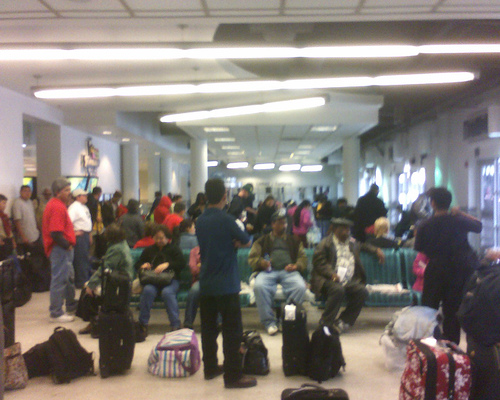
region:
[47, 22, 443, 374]
this is a transit area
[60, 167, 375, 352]
these people are waiting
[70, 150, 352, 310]
this is a group of people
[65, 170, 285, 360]
the people are traveling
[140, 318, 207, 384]
these are traveling bags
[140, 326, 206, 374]
the bag is striped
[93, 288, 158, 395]
this luggage is black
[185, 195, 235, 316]
this is a man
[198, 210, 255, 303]
the man has a blue shirt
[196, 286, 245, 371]
the man has black pants on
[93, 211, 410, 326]
people sitting on a bench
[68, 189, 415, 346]
people sitting on a bench at a airport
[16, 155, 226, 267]
people standing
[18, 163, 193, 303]
people standing at a airport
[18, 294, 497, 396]
bags and suitcases on the floor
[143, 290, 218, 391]
a striped duffle bag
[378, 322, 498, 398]
a red and black suitcase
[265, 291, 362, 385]
two black suitcases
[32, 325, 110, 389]
a black backpack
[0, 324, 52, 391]
a cheetah print bag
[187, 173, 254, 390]
man standing in middle of airport with arms crossed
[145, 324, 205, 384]
purple and blue striped dufle bag on ground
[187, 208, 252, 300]
blue shirt on man standing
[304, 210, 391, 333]
man sitting on green bench in brown hat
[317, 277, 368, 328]
brown trousers on black man sitting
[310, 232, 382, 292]
brown jacket on black man with white shirt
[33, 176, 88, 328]
man standing with red shirt and blue jeans with hand in pocket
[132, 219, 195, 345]
woman sitting with blue jeans and black coat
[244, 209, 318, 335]
African American man sitting in blue jeans holding water bottle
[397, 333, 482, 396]
red floral luggage in foreground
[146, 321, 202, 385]
Rainbow bag on the ground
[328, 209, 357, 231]
man wearing a black hat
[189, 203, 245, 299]
man wearing a blue shirt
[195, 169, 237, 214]
man with black hair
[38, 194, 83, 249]
man wearing a red shirt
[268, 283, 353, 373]
luggage on the ground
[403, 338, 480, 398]
red luggage on the ground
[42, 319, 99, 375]
backpack on the ground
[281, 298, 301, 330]
tag on a suitcase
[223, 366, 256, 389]
man wearing brown shoes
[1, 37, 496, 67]
bright white fluorescent tube lighting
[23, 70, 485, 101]
bright white fluorescent tube lighting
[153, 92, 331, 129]
bright white fluorescent tube lighting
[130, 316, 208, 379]
purple, yellow, and blue striped duffle bag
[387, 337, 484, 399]
red and white floral print suit case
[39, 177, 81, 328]
man wearing a red tee shirt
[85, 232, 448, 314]
long padded teal benches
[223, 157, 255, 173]
bright white fluorescent tube lighting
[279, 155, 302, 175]
bright white fluorescent tube lighting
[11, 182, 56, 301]
tall man in a large grey tee shirt